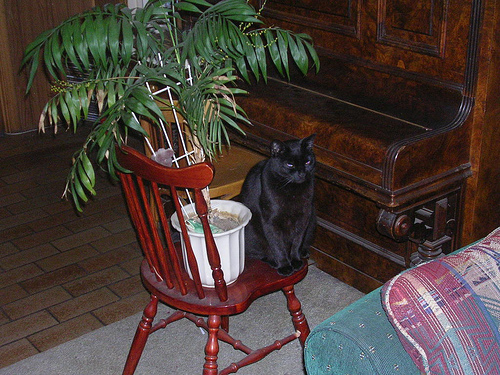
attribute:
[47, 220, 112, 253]
tile —  brown,  rectangle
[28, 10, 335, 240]
palm tree — miniature ,  palm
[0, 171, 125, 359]
floor — Ceramic ,  brown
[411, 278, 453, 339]
symbols — white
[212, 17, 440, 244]
wooden piano — brown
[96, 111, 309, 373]
chair — Wooden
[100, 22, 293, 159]
plants — green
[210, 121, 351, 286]
cat — black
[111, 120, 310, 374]
chair — shiny, wooden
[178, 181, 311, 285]
pot — White ,  ceramic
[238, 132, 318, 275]
cat — black ,  sitting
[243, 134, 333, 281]
cat — black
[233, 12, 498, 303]
piano — antique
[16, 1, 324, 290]
plant — green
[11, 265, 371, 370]
carpet — gray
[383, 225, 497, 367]
pillow — striped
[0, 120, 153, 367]
floor — brown ,  brick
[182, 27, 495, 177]
piano — brown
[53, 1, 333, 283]
plant — white, potted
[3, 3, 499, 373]
living room — nice ,  quiet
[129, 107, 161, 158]
wire — white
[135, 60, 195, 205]
wire — white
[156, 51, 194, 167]
wire — white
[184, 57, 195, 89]
wire — white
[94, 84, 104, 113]
leaf — dead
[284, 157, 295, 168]
eye — yellow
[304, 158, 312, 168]
eye — yellow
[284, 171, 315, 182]
whiskers — white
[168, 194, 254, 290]
pot — white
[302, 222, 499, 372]
couch — blue